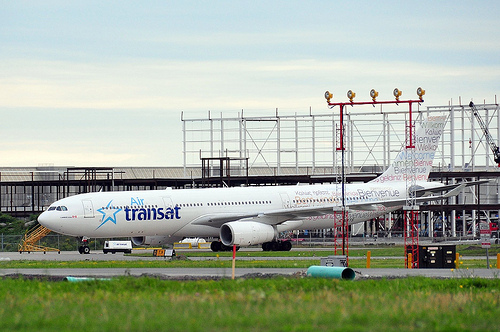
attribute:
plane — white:
[27, 114, 460, 267]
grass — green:
[2, 241, 490, 331]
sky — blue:
[1, 0, 495, 163]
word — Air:
[126, 196, 147, 208]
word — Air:
[127, 185, 147, 208]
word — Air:
[132, 193, 145, 209]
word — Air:
[126, 192, 154, 212]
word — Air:
[126, 192, 146, 209]